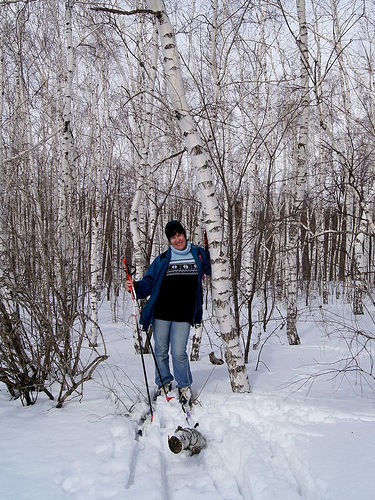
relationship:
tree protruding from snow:
[167, 423, 213, 464] [132, 384, 303, 497]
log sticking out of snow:
[164, 421, 205, 457] [137, 397, 301, 497]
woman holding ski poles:
[118, 215, 214, 405] [118, 254, 174, 423]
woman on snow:
[118, 215, 214, 405] [89, 346, 277, 474]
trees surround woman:
[9, 9, 374, 309] [118, 215, 214, 405]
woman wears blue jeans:
[118, 215, 214, 405] [150, 318, 193, 393]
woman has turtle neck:
[118, 215, 214, 405] [168, 243, 191, 257]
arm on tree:
[202, 248, 214, 275] [205, 174, 252, 400]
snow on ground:
[51, 398, 321, 498] [9, 322, 373, 499]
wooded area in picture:
[2, 3, 374, 390] [4, 4, 373, 494]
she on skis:
[121, 217, 212, 405] [130, 384, 199, 441]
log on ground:
[164, 421, 205, 457] [81, 364, 288, 499]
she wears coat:
[121, 217, 212, 405] [129, 244, 213, 328]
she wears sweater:
[118, 217, 212, 410] [129, 244, 217, 324]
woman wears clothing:
[118, 215, 214, 405] [134, 243, 213, 390]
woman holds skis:
[118, 215, 214, 405] [124, 279, 214, 419]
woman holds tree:
[118, 215, 214, 405] [199, 192, 250, 393]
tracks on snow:
[122, 427, 171, 493] [35, 425, 123, 497]